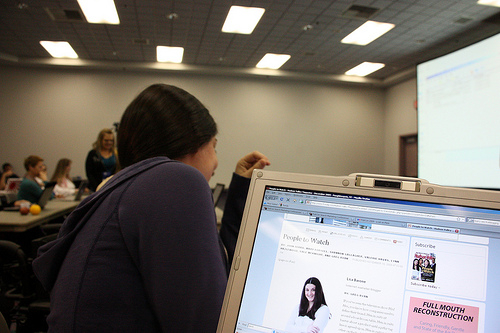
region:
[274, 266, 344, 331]
a woman on a computer screen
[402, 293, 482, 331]
pink advertisement on a computer screen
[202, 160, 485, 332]
a computer screen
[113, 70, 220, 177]
shiny brown hair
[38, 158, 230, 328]
a purple sweatshirt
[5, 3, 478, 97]
lights on the ceiling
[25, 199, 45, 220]
an orange on the desk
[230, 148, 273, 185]
a womans hand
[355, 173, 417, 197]
top of the laptop screen latch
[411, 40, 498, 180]
projector on the wall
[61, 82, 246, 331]
woman in blue shirt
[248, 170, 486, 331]
screen of open laptop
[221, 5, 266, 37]
rectangle light on ceiling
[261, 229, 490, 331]
image on computer screen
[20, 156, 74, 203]
people sitting at table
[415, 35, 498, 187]
giant white glowing screen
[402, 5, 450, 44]
gray squares on ceiling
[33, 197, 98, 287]
hood on back of shirt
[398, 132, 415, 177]
corner of closed door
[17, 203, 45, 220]
fruit on table top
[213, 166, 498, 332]
Computer monitor with web page displayed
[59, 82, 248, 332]
Person wearing skull cap and hoodie top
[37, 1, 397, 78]
Ceiling overhead rectangular white lights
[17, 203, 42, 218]
Apple and orange fruit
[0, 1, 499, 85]
Ceiling square tiles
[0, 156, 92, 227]
People sitting down at desks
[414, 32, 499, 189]
Large projection screen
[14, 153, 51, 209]
Man with right hand near face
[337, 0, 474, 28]
Ceiling ventilation vents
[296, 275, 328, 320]
Woman with center parted long dark hair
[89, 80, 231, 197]
Woman has dark colored hair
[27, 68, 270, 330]
Woman is in the foreground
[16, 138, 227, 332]
Woman is wearing a hoodie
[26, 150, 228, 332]
Woman is wearing a purple hoodie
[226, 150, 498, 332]
Computer screen is on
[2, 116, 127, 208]
People in the background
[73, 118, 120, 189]
Woman in the background has blonde hair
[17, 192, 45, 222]
Fruit is on the table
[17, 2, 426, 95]
Lights are on the ceiling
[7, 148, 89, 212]
Two laptops in the background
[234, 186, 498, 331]
screen on the computer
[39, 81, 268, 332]
woman sitting behind the computer screen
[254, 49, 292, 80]
flourescent light on the ceiling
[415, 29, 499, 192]
projector screen on the wall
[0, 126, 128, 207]
people sitting in the background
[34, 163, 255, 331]
navy blue hooded shirt on the woman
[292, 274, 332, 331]
picture of a woman on the computer screen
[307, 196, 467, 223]
url box on the internet browser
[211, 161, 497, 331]
silver laptop screen turned on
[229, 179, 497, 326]
website open on the laptop screen